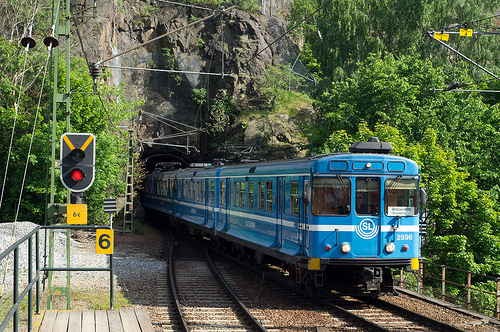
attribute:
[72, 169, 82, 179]
light — red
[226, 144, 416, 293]
train — coming out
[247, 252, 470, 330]
tracks — set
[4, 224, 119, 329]
rails — green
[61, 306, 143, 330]
planks — brown, wooden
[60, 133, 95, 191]
light — red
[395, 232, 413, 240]
number — white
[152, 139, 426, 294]
train — blue, moving, white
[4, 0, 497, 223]
mountain — big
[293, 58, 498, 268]
trees — green